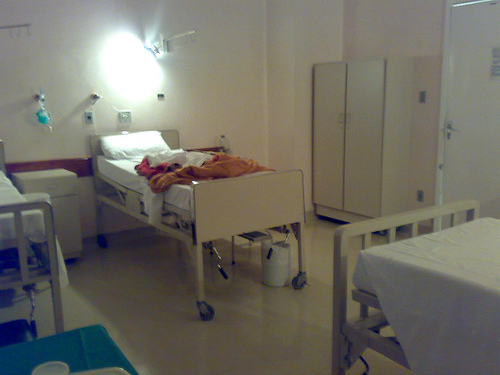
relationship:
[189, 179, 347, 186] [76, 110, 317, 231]
end of bed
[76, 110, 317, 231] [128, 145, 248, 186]
bed with clothes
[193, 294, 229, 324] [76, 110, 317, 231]
wheel on bed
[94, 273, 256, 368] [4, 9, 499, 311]
floor of room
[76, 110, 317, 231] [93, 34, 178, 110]
hospital bed with light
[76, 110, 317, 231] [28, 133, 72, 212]
bed to left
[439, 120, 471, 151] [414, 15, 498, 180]
lever of door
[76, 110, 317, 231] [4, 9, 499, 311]
bed in room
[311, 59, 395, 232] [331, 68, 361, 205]
closet with doors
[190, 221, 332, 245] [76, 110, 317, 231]
foot of bed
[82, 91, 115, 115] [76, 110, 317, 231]
stand by bed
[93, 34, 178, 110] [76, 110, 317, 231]
light above bed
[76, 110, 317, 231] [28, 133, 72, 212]
bed on left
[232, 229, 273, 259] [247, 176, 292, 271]
footstool next to bed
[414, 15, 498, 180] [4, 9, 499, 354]
door in room